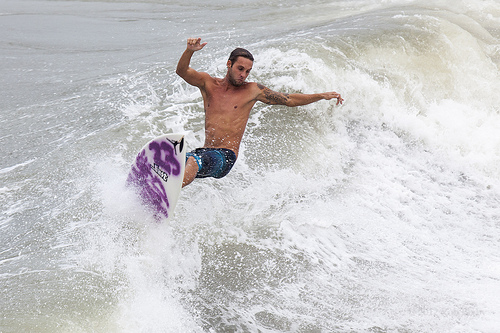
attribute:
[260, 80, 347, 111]
arm — stretching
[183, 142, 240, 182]
shorts — dark, blue, black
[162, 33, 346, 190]
man — standing, surfing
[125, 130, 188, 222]
surfboard — white, small, purple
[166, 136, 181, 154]
logo — black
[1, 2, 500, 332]
water — foamy, raging, splashing, choppy, active, grey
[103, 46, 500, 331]
wave — large, big, white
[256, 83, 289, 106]
tattoo — large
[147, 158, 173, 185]
emblem — black, Nike Jordan